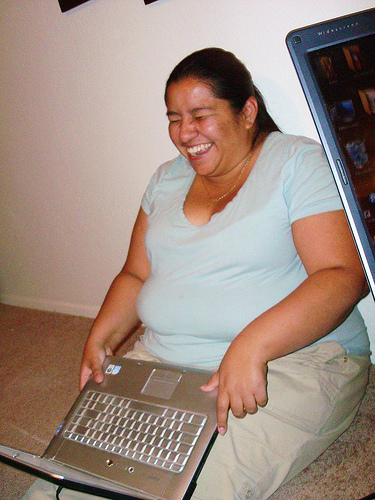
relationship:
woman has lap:
[78, 47, 369, 497] [36, 352, 327, 498]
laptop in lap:
[0, 354, 216, 498] [36, 352, 327, 498]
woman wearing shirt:
[79, 47, 367, 496] [140, 131, 370, 364]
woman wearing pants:
[79, 47, 367, 496] [21, 338, 370, 498]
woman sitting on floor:
[79, 47, 367, 496] [0, 304, 373, 498]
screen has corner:
[307, 33, 373, 238] [307, 32, 372, 132]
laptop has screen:
[285, 5, 374, 299] [307, 33, 373, 238]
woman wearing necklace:
[79, 47, 367, 496] [200, 150, 250, 201]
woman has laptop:
[79, 47, 367, 496] [0, 354, 216, 498]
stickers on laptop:
[104, 363, 120, 373] [0, 354, 216, 498]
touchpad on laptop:
[140, 368, 184, 398] [0, 354, 216, 498]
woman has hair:
[79, 47, 367, 496] [164, 47, 282, 149]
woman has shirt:
[79, 47, 367, 496] [140, 131, 370, 364]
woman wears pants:
[79, 47, 367, 496] [21, 338, 370, 498]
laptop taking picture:
[283, 4, 374, 295] [1, 5, 318, 317]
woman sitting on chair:
[79, 47, 367, 496] [6, 304, 371, 493]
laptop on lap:
[0, 354, 216, 498] [90, 339, 330, 495]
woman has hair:
[79, 47, 367, 496] [163, 47, 282, 134]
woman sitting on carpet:
[79, 47, 367, 496] [0, 302, 362, 499]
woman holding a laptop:
[79, 47, 367, 496] [0, 354, 216, 498]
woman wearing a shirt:
[79, 47, 367, 496] [140, 131, 370, 364]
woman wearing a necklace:
[79, 47, 367, 496] [199, 145, 253, 202]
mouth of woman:
[186, 139, 213, 158] [79, 47, 367, 496]